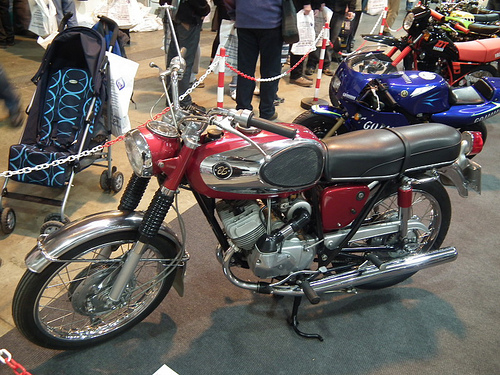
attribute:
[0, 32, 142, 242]
stroller — black and blue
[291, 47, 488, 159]
motorcycle — blue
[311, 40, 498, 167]
motorcycle — red and black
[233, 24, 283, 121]
pants — black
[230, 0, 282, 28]
shirt — blue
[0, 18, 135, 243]
stroller — blue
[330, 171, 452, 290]
wheel — rear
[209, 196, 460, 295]
engine — silver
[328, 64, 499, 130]
engine — silver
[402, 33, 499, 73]
engine — silver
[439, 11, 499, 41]
engine — silver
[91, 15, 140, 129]
backpack — blue and black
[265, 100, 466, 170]
seat — long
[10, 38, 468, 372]
motorcycle — black and orange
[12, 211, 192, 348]
wheels — chrome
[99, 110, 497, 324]
motorcycle — red and gray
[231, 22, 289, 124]
pants — black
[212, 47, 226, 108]
pole — red and white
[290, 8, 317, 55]
bag — white, plastic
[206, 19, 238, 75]
bag — white, plastic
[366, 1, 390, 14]
bag — white, plastic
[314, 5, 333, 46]
bag — white, plastic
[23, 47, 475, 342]
bike — red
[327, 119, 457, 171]
seat — leather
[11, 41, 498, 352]
motorcycle — red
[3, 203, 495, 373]
carpeting — grey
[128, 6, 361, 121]
poles — red and white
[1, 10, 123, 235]
stroller — blue, black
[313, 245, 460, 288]
tailpipe — chrome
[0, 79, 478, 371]
motorcycle — red, red and black, blue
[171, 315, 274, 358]
ground — gray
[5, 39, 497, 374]
floor — wooden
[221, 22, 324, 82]
chain — red and white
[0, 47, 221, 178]
chain — red and white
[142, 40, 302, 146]
handlebars — red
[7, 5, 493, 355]
bike — red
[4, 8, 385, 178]
chain — red and white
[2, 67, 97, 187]
circles — blue, intertwined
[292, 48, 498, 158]
vehicle — designed, blue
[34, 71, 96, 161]
writing —  red or blue